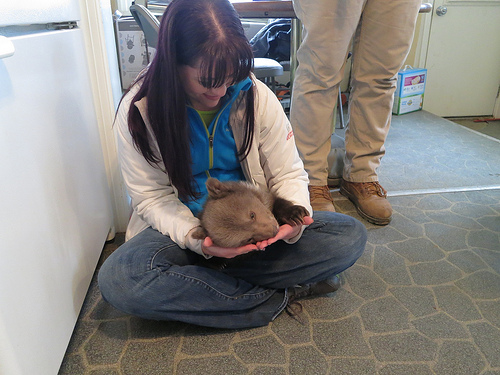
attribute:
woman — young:
[92, 11, 363, 318]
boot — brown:
[337, 168, 395, 227]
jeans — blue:
[86, 207, 385, 339]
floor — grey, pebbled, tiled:
[398, 112, 498, 221]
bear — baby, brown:
[185, 173, 325, 258]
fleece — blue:
[168, 74, 255, 212]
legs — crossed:
[107, 219, 370, 334]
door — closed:
[422, 7, 488, 122]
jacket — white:
[97, 91, 320, 262]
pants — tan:
[294, 10, 412, 184]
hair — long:
[143, 5, 268, 187]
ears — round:
[191, 174, 228, 239]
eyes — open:
[234, 209, 260, 255]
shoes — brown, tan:
[299, 168, 406, 231]